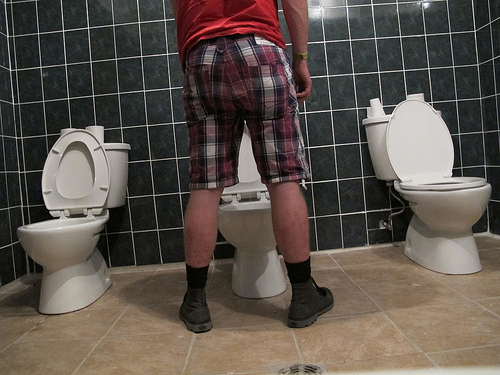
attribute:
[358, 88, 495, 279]
toilet — white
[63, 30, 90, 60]
tile — black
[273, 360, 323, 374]
drain — black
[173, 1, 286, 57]
shirt — red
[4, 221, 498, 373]
ground — tiled, tan colored